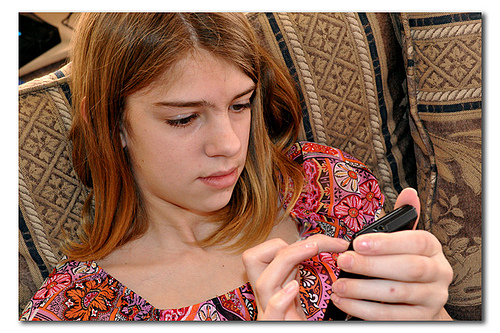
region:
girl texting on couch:
[24, 17, 472, 308]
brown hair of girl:
[67, 19, 295, 250]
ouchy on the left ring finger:
[390, 283, 399, 303]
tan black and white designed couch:
[264, 18, 471, 297]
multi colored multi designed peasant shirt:
[64, 146, 398, 318]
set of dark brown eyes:
[150, 96, 262, 123]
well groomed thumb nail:
[399, 186, 419, 197]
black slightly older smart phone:
[310, 204, 412, 312]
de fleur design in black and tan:
[38, 175, 79, 209]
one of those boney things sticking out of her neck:
[171, 217, 203, 257]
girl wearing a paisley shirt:
[13, 10, 495, 325]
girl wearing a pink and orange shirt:
[23, 14, 473, 331]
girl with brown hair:
[8, 12, 469, 330]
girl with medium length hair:
[10, 14, 485, 331]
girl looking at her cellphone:
[25, 10, 460, 331]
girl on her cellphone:
[39, 10, 448, 328]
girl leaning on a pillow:
[0, 8, 481, 329]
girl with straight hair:
[16, 0, 463, 322]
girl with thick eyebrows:
[20, 12, 471, 331]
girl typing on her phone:
[21, 11, 483, 331]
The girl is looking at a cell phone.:
[166, 102, 415, 317]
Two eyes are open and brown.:
[166, 101, 249, 124]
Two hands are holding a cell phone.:
[242, 186, 452, 317]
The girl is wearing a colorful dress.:
[20, 145, 385, 321]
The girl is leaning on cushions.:
[20, 12, 479, 322]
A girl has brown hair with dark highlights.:
[73, 14, 302, 261]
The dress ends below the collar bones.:
[83, 153, 302, 309]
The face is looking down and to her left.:
[120, 47, 255, 209]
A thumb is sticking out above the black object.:
[396, 187, 419, 229]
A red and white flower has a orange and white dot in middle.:
[334, 192, 365, 231]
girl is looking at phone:
[18, 10, 455, 328]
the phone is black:
[287, 172, 451, 331]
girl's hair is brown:
[38, 6, 324, 246]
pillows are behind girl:
[23, 14, 498, 301]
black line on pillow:
[268, 10, 335, 146]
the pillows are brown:
[13, 14, 499, 323]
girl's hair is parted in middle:
[173, 9, 205, 60]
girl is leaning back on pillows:
[35, 14, 455, 309]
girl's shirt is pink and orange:
[18, 145, 390, 330]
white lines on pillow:
[278, 18, 350, 152]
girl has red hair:
[62, 13, 307, 260]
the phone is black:
[319, 200, 426, 319]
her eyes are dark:
[155, 93, 259, 132]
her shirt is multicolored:
[23, 10, 398, 322]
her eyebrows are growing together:
[152, 84, 257, 113]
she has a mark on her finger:
[329, 185, 455, 320]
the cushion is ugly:
[408, 15, 481, 319]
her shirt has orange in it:
[23, 12, 391, 317]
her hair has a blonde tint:
[65, 10, 300, 260]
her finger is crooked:
[241, 230, 352, 318]